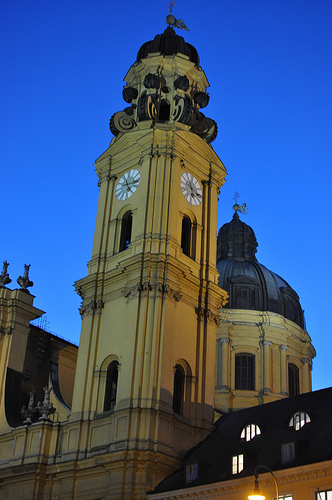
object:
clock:
[113, 167, 141, 203]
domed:
[130, 22, 207, 66]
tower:
[211, 193, 316, 402]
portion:
[146, 385, 330, 498]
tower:
[64, 1, 231, 425]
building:
[1, 1, 329, 497]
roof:
[216, 212, 306, 329]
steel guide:
[103, 6, 224, 139]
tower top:
[104, 4, 240, 158]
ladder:
[36, 314, 48, 369]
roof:
[0, 323, 78, 350]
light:
[246, 466, 281, 499]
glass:
[217, 194, 304, 336]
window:
[89, 350, 123, 414]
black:
[190, 428, 224, 459]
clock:
[173, 169, 204, 209]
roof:
[108, 27, 219, 141]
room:
[232, 276, 265, 309]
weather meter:
[165, 3, 190, 33]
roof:
[149, 386, 331, 496]